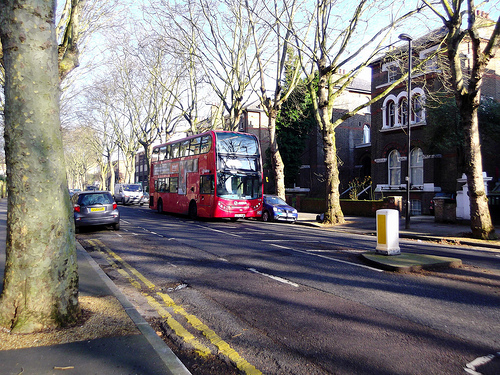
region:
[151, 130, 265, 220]
Red double decker bus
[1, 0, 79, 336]
Trunk of a tree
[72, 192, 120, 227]
Back of blue car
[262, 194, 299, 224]
Front of blue car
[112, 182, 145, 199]
SUV in back of double decker bus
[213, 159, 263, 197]
Front windshield of the red bus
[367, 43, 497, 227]
Blue gray building trimmed in white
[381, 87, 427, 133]
Custom windows trimmed in white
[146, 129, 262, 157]
Top deck of the double decker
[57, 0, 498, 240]
Tree lined street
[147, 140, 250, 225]
this is a bus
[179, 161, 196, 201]
the bus is red in color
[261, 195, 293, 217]
this is a car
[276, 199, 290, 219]
the car is blue in color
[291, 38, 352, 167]
this is a tree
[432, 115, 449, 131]
the leaves are green in color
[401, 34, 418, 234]
this is a pole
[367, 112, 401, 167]
this is a building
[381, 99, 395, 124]
this is a window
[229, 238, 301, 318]
this is a road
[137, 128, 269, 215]
double decker bus on street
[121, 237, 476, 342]
street for vehicles to travel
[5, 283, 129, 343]
earth space at base of tree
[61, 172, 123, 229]
vehicle on side of road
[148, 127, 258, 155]
upper level of bus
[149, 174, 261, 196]
lower level of bus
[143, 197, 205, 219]
tires on the bus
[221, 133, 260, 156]
top front window of bus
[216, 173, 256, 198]
botton front window of bus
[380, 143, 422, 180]
arched windows on building